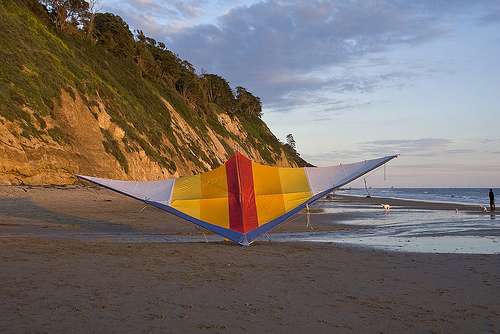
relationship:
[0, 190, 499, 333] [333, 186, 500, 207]
beach meets water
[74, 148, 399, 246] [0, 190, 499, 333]
kite on beach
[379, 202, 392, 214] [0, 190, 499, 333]
dog on beach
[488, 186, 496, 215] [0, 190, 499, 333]
person standing on beach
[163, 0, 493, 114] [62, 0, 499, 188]
cloud in sky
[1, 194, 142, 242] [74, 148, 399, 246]
shadow from kite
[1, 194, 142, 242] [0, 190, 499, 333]
shadow on beach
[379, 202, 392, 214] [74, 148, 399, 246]
dog behind kite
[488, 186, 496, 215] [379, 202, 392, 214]
person walking dog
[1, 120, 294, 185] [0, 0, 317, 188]
dirt on hill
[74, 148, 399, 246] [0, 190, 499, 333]
kite resting on beach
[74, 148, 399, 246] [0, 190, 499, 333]
kite landed on beach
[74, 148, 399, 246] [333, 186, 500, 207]
kite close to water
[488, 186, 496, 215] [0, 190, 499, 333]
person on beach